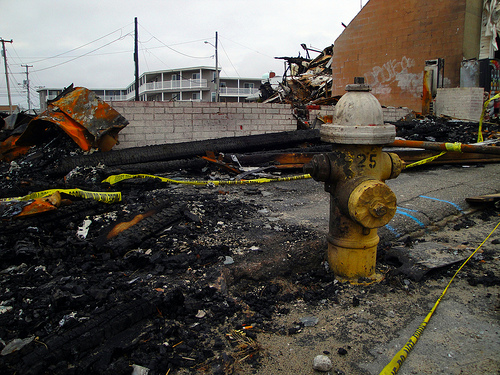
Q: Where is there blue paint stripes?
A: On a curb.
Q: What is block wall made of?
A: Concrete.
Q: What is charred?
A: A length of charred wood.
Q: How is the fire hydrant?
A: Blackened.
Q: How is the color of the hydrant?
A: Yellow.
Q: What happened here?
A: Fire.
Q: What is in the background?
A: Building.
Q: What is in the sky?
A: Powerlines.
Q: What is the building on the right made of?
A: Brick.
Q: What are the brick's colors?
A: Brown.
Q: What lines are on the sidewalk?
A: Blue chalk.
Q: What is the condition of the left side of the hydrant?
A: Burnt.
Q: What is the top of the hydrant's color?
A: White.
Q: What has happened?
A: Fire.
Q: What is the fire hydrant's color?
A: Yellow.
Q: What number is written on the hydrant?
A: 25.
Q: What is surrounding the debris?
A: Caution tape.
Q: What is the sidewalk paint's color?
A: Blue.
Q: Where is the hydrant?
A: In the road.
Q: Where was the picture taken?
A: Outside after a fire.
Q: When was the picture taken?
A: In the daytime.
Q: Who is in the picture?
A: No one.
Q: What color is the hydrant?
A: Yellow and white.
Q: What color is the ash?
A: Black.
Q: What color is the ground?
A: Gray.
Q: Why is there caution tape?
A: To frame the dangerous area.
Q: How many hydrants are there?
A: 1.